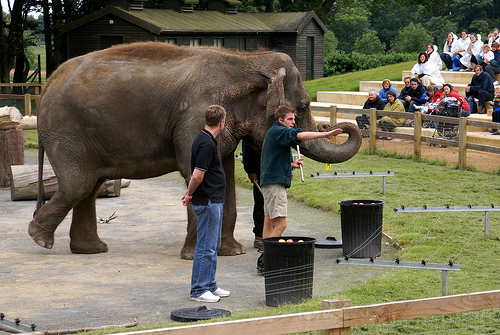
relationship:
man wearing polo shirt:
[182, 104, 229, 302] [186, 130, 226, 207]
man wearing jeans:
[182, 104, 229, 302] [190, 201, 221, 293]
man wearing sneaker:
[182, 104, 229, 302] [191, 290, 220, 301]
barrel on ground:
[261, 236, 316, 306] [1, 59, 499, 330]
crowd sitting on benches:
[356, 30, 497, 140] [310, 63, 499, 151]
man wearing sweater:
[256, 105, 343, 275] [258, 120, 300, 189]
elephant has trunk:
[28, 40, 361, 258] [288, 71, 361, 161]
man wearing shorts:
[256, 105, 343, 275] [262, 184, 288, 218]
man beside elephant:
[182, 104, 229, 302] [28, 40, 361, 258]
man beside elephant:
[256, 105, 343, 275] [28, 40, 361, 258]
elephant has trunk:
[28, 40, 361, 258] [292, 90, 362, 164]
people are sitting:
[353, 54, 498, 200] [418, 130, 458, 150]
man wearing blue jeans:
[182, 104, 233, 302] [191, 213, 214, 314]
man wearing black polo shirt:
[182, 104, 233, 302] [186, 133, 232, 223]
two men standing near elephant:
[174, 100, 311, 317] [67, 101, 180, 158]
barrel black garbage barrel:
[261, 236, 316, 306] [261, 236, 316, 306]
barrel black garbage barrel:
[339, 198, 384, 258] [339, 198, 384, 258]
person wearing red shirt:
[428, 89, 474, 104] [453, 108, 469, 113]